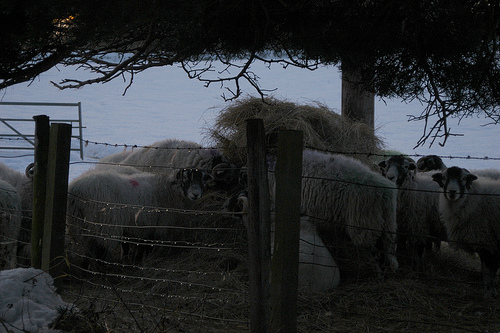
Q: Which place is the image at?
A: It is at the pen.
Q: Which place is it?
A: It is a pen.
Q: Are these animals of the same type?
A: Yes, all the animals are sheep.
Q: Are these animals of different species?
A: No, all the animals are sheep.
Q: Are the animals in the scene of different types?
A: No, all the animals are sheep.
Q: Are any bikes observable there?
A: No, there are no bikes.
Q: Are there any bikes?
A: No, there are no bikes.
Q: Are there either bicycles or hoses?
A: No, there are no bicycles or hoses.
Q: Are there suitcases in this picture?
A: No, there are no suitcases.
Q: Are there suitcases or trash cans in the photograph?
A: No, there are no suitcases or trash cans.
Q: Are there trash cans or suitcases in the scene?
A: No, there are no suitcases or trash cans.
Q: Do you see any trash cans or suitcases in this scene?
A: No, there are no suitcases or trash cans.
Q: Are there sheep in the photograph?
A: Yes, there is a sheep.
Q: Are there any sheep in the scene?
A: Yes, there is a sheep.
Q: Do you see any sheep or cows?
A: Yes, there is a sheep.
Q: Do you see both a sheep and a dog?
A: No, there is a sheep but no dogs.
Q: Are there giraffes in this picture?
A: No, there are no giraffes.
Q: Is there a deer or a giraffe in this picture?
A: No, there are no giraffes or deer.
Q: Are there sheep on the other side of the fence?
A: Yes, there is a sheep on the other side of the fence.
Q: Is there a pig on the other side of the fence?
A: No, there is a sheep on the other side of the fence.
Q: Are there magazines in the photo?
A: No, there are no magazines.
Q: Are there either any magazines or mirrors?
A: No, there are no magazines or mirrors.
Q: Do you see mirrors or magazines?
A: No, there are no magazines or mirrors.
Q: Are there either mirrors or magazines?
A: No, there are no magazines or mirrors.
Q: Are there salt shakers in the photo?
A: No, there are no salt shakers.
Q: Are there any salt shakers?
A: No, there are no salt shakers.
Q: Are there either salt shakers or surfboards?
A: No, there are no salt shakers or surfboards.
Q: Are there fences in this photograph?
A: Yes, there is a fence.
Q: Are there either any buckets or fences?
A: Yes, there is a fence.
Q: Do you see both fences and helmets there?
A: No, there is a fence but no helmets.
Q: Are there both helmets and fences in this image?
A: No, there is a fence but no helmets.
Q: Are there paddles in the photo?
A: No, there are no paddles.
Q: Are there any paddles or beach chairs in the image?
A: No, there are no paddles or beach chairs.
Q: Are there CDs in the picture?
A: No, there are no cds.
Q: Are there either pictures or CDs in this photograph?
A: No, there are no CDs or pictures.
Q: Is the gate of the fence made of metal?
A: Yes, the gate is made of metal.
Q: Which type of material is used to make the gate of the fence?
A: The gate is made of metal.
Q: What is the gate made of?
A: The gate is made of metal.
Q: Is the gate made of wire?
A: No, the gate is made of metal.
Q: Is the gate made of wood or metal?
A: The gate is made of metal.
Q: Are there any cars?
A: No, there are no cars.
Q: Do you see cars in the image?
A: No, there are no cars.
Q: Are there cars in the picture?
A: No, there are no cars.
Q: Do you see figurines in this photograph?
A: No, there are no figurines.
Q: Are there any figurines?
A: No, there are no figurines.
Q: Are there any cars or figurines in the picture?
A: No, there are no figurines or cars.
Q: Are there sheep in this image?
A: Yes, there is a sheep.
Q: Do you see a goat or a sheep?
A: Yes, there is a sheep.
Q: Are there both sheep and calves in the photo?
A: No, there is a sheep but no calves.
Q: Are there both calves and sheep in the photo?
A: No, there is a sheep but no calves.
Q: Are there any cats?
A: No, there are no cats.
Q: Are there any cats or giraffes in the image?
A: No, there are no cats or giraffes.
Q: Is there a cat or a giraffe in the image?
A: No, there are no cats or giraffes.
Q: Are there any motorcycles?
A: No, there are no motorcycles.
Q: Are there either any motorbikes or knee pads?
A: No, there are no motorbikes or knee pads.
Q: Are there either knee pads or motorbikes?
A: No, there are no motorbikes or knee pads.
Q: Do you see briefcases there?
A: No, there are no briefcases.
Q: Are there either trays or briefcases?
A: No, there are no briefcases or trays.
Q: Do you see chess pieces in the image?
A: No, there are no chess pieces.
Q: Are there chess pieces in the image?
A: No, there are no chess pieces.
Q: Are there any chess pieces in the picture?
A: No, there are no chess pieces.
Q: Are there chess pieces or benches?
A: No, there are no chess pieces or benches.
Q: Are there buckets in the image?
A: No, there are no buckets.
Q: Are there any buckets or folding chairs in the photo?
A: No, there are no buckets or folding chairs.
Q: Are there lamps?
A: No, there are no lamps.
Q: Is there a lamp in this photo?
A: No, there are no lamps.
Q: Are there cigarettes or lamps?
A: No, there are no lamps or cigarettes.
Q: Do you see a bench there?
A: No, there are no benches.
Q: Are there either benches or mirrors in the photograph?
A: No, there are no benches or mirrors.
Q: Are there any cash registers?
A: No, there are no cash registers.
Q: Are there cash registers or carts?
A: No, there are no cash registers or carts.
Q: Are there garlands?
A: No, there are no garlands.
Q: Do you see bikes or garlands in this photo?
A: No, there are no garlands or bikes.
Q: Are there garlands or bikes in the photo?
A: No, there are no garlands or bikes.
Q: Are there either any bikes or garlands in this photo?
A: No, there are no garlands or bikes.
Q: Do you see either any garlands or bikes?
A: No, there are no garlands or bikes.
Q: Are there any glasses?
A: No, there are no glasses.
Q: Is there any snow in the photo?
A: Yes, there is snow.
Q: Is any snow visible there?
A: Yes, there is snow.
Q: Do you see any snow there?
A: Yes, there is snow.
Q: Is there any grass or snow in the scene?
A: Yes, there is snow.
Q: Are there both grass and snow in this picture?
A: No, there is snow but no grass.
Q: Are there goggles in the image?
A: No, there are no goggles.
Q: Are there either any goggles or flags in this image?
A: No, there are no goggles or flags.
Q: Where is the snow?
A: The snow is on the ground.